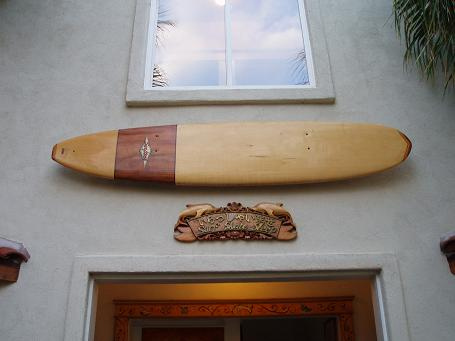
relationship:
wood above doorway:
[31, 91, 426, 230] [87, 249, 347, 326]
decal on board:
[122, 139, 165, 161] [31, 91, 426, 230]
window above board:
[146, 5, 324, 99] [31, 91, 426, 230]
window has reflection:
[146, 5, 324, 99] [166, 15, 287, 83]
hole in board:
[292, 120, 324, 159] [31, 91, 426, 230]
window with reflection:
[146, 5, 324, 99] [166, 15, 287, 83]